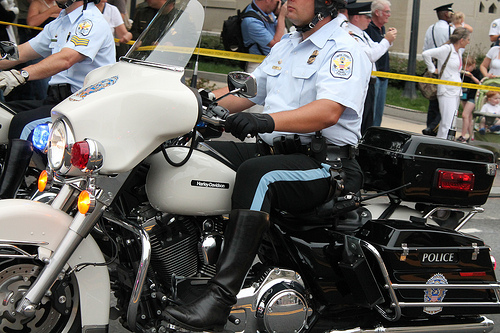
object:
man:
[0, 0, 116, 202]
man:
[342, 1, 398, 136]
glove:
[224, 112, 275, 141]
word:
[423, 251, 456, 262]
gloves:
[197, 88, 217, 101]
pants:
[203, 143, 336, 222]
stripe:
[250, 162, 331, 210]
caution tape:
[0, 15, 500, 94]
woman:
[421, 26, 473, 139]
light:
[70, 136, 104, 172]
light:
[47, 113, 77, 175]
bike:
[0, 0, 497, 333]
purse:
[416, 44, 453, 101]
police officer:
[420, 2, 455, 136]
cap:
[433, 2, 453, 13]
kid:
[479, 90, 500, 135]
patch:
[70, 18, 94, 46]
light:
[38, 170, 48, 193]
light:
[77, 190, 96, 215]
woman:
[480, 37, 500, 76]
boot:
[156, 209, 272, 333]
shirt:
[28, 2, 116, 94]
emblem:
[70, 19, 93, 47]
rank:
[69, 34, 89, 47]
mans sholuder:
[72, 13, 112, 54]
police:
[422, 253, 454, 264]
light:
[433, 168, 476, 194]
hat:
[346, 0, 373, 17]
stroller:
[473, 76, 500, 142]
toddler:
[479, 89, 500, 136]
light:
[31, 122, 50, 156]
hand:
[225, 112, 276, 142]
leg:
[216, 157, 339, 276]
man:
[156, 0, 372, 333]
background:
[0, 0, 499, 135]